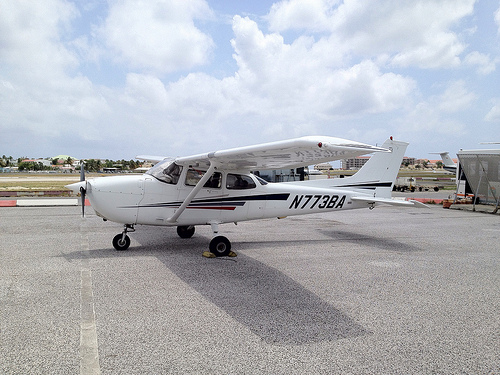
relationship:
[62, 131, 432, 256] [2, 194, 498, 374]
plane on top of ground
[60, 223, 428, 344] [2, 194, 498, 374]
shadow on top of ground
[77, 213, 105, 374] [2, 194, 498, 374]
line painted on ground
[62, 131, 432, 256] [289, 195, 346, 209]
plane has number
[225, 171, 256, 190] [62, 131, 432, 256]
window on side of plane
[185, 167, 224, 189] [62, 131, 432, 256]
window on side of plane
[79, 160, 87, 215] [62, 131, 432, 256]
propeller in front of plane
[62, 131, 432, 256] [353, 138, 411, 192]
plane has tail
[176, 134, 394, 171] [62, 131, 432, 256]
wing on left of plane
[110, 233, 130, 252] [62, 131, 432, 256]
tire in front of plane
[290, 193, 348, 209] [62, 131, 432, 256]
writing on side of plane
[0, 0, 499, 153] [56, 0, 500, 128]
clouds in front of sky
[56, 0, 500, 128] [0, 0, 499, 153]
sky behind clouds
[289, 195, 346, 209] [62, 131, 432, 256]
number written on plane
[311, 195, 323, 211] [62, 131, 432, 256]
number written on plane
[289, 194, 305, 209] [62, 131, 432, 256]
letter written on plane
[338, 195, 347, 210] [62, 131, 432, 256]
letter written on plane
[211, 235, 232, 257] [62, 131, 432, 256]
tire on bottom of plane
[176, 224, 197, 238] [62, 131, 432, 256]
tire on bottom of plane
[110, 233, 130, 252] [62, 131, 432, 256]
tire on bottom of plane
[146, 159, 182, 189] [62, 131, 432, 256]
cockpit inside of plane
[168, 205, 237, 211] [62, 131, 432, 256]
stripe on side of plane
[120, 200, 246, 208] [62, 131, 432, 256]
stripe on side of plane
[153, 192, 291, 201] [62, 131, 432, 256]
stripe on side of plane